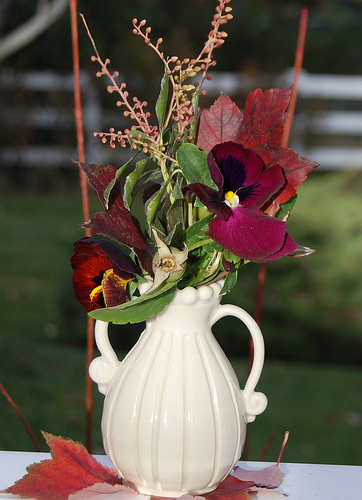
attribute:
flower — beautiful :
[232, 83, 295, 148]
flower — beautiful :
[249, 141, 319, 226]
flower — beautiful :
[67, 231, 144, 314]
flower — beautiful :
[90, 50, 178, 200]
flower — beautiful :
[177, 136, 298, 263]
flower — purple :
[192, 117, 332, 226]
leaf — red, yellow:
[171, 134, 219, 206]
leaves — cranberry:
[0, 419, 316, 498]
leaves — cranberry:
[67, 68, 327, 344]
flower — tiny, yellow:
[208, 162, 297, 241]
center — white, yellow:
[222, 189, 239, 211]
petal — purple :
[205, 206, 285, 259]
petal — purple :
[180, 179, 233, 220]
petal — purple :
[205, 139, 263, 202]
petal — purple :
[238, 161, 287, 210]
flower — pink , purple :
[172, 135, 352, 330]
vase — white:
[87, 273, 268, 497]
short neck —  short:
[140, 300, 219, 332]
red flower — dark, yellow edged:
[65, 232, 141, 314]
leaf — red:
[232, 82, 293, 147]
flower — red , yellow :
[67, 235, 151, 311]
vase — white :
[92, 240, 275, 494]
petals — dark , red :
[70, 235, 106, 299]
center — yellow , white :
[221, 188, 238, 209]